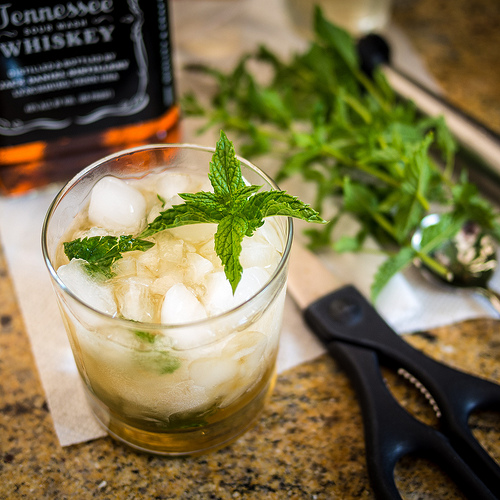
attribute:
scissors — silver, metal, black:
[277, 236, 497, 497]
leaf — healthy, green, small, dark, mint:
[145, 127, 331, 294]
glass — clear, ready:
[28, 132, 340, 461]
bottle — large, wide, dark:
[4, 3, 198, 195]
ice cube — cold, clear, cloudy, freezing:
[88, 174, 144, 230]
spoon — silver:
[291, 2, 498, 180]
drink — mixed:
[53, 161, 278, 432]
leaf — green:
[179, 158, 278, 264]